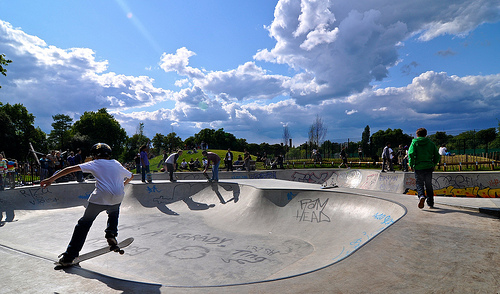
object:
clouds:
[0, 0, 498, 142]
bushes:
[272, 123, 499, 159]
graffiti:
[293, 190, 337, 226]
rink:
[1, 182, 406, 287]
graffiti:
[90, 214, 283, 266]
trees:
[0, 101, 133, 158]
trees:
[158, 124, 287, 164]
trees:
[362, 126, 416, 145]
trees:
[432, 125, 498, 154]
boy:
[406, 125, 441, 210]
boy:
[159, 149, 182, 182]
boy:
[132, 142, 157, 185]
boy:
[197, 145, 221, 185]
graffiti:
[409, 171, 495, 195]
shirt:
[74, 152, 131, 206]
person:
[407, 126, 442, 208]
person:
[198, 149, 222, 181]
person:
[162, 147, 182, 182]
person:
[138, 144, 149, 183]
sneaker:
[411, 195, 441, 210]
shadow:
[183, 195, 218, 212]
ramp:
[2, 172, 406, 292]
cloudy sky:
[236, 19, 353, 120]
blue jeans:
[410, 165, 444, 208]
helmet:
[90, 140, 114, 155]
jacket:
[401, 136, 444, 170]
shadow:
[73, 257, 164, 294]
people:
[0, 114, 447, 270]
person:
[44, 130, 148, 276]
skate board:
[49, 236, 141, 270]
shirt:
[201, 153, 226, 166]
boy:
[46, 141, 145, 269]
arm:
[38, 163, 90, 188]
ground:
[0, 178, 498, 292]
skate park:
[0, 129, 500, 294]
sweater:
[407, 136, 442, 173]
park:
[1, 161, 498, 291]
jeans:
[61, 203, 122, 258]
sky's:
[273, 27, 349, 90]